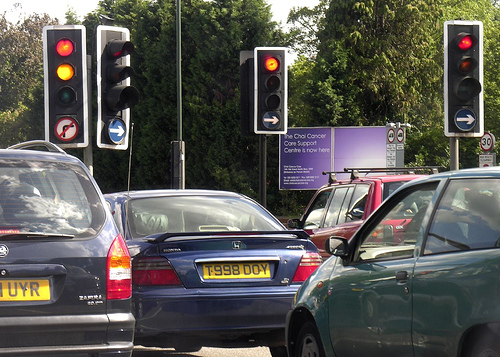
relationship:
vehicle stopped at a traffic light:
[0, 147, 136, 356] [42, 22, 92, 149]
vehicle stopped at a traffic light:
[103, 186, 323, 356] [94, 20, 137, 155]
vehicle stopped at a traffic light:
[287, 168, 438, 266] [251, 44, 287, 137]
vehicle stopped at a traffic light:
[282, 167, 499, 357] [442, 18, 486, 139]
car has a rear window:
[102, 188, 327, 349] [123, 195, 293, 239]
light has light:
[38, 28, 89, 152] [56, 40, 74, 57]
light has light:
[426, 15, 496, 152] [458, 36, 472, 50]